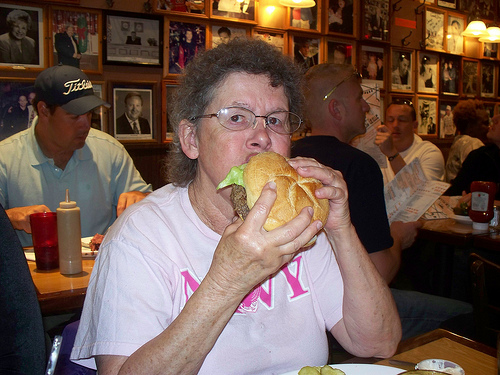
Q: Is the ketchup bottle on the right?
A: Yes, the ketchup bottle is on the right of the image.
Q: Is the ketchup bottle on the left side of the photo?
A: No, the ketchup bottle is on the right of the image.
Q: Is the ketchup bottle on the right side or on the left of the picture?
A: The ketchup bottle is on the right of the image.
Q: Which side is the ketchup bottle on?
A: The ketchup bottle is on the right of the image.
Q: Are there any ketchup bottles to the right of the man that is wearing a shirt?
A: Yes, there is a ketchup bottle to the right of the man.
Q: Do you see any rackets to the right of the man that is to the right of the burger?
A: No, there is a ketchup bottle to the right of the man.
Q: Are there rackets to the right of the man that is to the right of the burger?
A: No, there is a ketchup bottle to the right of the man.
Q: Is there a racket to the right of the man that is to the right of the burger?
A: No, there is a ketchup bottle to the right of the man.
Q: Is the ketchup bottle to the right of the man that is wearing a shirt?
A: Yes, the ketchup bottle is to the right of the man.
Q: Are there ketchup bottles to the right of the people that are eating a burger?
A: Yes, there is a ketchup bottle to the right of the people.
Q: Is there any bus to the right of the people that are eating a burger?
A: No, there is a ketchup bottle to the right of the people.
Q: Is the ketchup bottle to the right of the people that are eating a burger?
A: Yes, the ketchup bottle is to the right of the people.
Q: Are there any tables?
A: Yes, there is a table.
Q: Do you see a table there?
A: Yes, there is a table.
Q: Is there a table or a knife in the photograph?
A: Yes, there is a table.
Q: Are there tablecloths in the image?
A: No, there are no tablecloths.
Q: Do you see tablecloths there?
A: No, there are no tablecloths.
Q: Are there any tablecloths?
A: No, there are no tablecloths.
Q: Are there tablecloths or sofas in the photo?
A: No, there are no tablecloths or sofas.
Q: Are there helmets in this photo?
A: No, there are no helmets.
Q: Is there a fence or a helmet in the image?
A: No, there are no helmets or fences.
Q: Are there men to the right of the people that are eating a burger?
A: Yes, there is a man to the right of the people.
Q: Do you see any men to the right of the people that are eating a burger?
A: Yes, there is a man to the right of the people.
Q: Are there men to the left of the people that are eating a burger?
A: No, the man is to the right of the people.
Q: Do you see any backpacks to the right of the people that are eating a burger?
A: No, there is a man to the right of the people.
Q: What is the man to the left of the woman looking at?
A: The man is looking at the menu.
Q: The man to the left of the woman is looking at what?
A: The man is looking at the menu.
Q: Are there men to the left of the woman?
A: Yes, there is a man to the left of the woman.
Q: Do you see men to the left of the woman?
A: Yes, there is a man to the left of the woman.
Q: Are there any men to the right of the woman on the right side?
A: No, the man is to the left of the woman.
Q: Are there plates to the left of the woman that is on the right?
A: No, there is a man to the left of the woman.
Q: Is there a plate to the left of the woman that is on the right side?
A: No, there is a man to the left of the woman.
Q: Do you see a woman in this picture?
A: Yes, there is a woman.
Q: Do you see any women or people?
A: Yes, there is a woman.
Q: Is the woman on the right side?
A: Yes, the woman is on the right of the image.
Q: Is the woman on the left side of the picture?
A: No, the woman is on the right of the image.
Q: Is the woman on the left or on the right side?
A: The woman is on the right of the image.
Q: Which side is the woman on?
A: The woman is on the right of the image.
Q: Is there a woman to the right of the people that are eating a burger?
A: Yes, there is a woman to the right of the people.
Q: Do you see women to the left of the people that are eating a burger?
A: No, the woman is to the right of the people.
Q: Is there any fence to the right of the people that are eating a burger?
A: No, there is a woman to the right of the people.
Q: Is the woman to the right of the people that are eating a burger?
A: Yes, the woman is to the right of the people.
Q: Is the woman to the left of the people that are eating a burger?
A: No, the woman is to the right of the people.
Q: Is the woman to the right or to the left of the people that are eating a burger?
A: The woman is to the right of the people.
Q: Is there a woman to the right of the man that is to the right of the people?
A: Yes, there is a woman to the right of the man.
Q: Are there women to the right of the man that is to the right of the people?
A: Yes, there is a woman to the right of the man.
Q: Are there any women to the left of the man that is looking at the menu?
A: No, the woman is to the right of the man.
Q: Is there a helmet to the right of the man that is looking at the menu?
A: No, there is a woman to the right of the man.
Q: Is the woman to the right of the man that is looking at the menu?
A: Yes, the woman is to the right of the man.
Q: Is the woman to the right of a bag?
A: No, the woman is to the right of the man.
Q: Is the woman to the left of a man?
A: No, the woman is to the right of a man.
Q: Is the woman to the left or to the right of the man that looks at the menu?
A: The woman is to the right of the man.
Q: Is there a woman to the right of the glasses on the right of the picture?
A: Yes, there is a woman to the right of the glasses.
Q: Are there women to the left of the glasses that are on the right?
A: No, the woman is to the right of the glasses.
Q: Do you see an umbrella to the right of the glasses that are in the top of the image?
A: No, there is a woman to the right of the glasses.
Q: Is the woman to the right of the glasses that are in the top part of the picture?
A: Yes, the woman is to the right of the glasses.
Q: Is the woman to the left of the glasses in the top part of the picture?
A: No, the woman is to the right of the glasses.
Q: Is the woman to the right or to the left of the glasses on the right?
A: The woman is to the right of the glasses.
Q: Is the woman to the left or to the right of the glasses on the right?
A: The woman is to the right of the glasses.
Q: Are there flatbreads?
A: No, there are no flatbreads.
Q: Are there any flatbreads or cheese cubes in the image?
A: No, there are no flatbreads or cheese cubes.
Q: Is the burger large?
A: Yes, the burger is large.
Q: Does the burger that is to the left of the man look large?
A: Yes, the burger is large.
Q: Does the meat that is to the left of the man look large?
A: Yes, the burger is large.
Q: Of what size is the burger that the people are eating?
A: The burger is large.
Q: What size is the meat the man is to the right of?
A: The burger is large.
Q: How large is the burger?
A: The burger is large.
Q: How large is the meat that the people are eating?
A: The burger is large.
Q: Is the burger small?
A: No, the burger is large.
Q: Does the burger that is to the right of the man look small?
A: No, the burger is large.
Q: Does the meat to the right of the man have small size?
A: No, the burger is large.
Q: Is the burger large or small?
A: The burger is large.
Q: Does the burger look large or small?
A: The burger is large.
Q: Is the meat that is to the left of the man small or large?
A: The burger is large.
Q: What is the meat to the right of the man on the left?
A: The meat is a burger.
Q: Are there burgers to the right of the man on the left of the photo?
A: Yes, there is a burger to the right of the man.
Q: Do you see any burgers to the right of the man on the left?
A: Yes, there is a burger to the right of the man.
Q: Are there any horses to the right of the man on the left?
A: No, there is a burger to the right of the man.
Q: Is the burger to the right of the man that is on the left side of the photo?
A: Yes, the burger is to the right of the man.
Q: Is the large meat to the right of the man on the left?
A: Yes, the burger is to the right of the man.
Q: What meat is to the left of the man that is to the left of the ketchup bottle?
A: The meat is a burger.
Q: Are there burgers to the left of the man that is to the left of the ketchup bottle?
A: Yes, there is a burger to the left of the man.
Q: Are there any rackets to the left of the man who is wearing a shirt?
A: No, there is a burger to the left of the man.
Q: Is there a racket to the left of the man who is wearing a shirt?
A: No, there is a burger to the left of the man.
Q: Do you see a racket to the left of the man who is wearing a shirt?
A: No, there is a burger to the left of the man.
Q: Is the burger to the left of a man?
A: Yes, the burger is to the left of a man.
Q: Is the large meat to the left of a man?
A: Yes, the burger is to the left of a man.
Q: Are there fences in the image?
A: No, there are no fences.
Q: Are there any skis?
A: No, there are no skis.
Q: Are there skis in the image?
A: No, there are no skis.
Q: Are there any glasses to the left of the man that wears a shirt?
A: Yes, there are glasses to the left of the man.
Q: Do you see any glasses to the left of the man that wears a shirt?
A: Yes, there are glasses to the left of the man.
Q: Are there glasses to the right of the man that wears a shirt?
A: No, the glasses are to the left of the man.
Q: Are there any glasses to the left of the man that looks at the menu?
A: Yes, there are glasses to the left of the man.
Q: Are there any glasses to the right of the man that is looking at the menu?
A: No, the glasses are to the left of the man.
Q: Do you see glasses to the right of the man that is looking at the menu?
A: No, the glasses are to the left of the man.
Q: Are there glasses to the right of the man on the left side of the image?
A: Yes, there are glasses to the right of the man.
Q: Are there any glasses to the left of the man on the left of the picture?
A: No, the glasses are to the right of the man.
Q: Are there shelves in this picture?
A: No, there are no shelves.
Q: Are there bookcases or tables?
A: Yes, there is a table.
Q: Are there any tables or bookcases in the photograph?
A: Yes, there is a table.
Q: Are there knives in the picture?
A: No, there are no knives.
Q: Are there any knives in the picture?
A: No, there are no knives.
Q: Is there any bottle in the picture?
A: Yes, there is a bottle.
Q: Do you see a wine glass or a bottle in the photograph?
A: Yes, there is a bottle.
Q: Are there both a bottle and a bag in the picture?
A: No, there is a bottle but no bags.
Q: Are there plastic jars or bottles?
A: Yes, there is a plastic bottle.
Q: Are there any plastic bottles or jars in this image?
A: Yes, there is a plastic bottle.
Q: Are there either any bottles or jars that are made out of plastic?
A: Yes, the bottle is made of plastic.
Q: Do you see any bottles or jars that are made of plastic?
A: Yes, the bottle is made of plastic.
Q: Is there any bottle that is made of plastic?
A: Yes, there is a bottle that is made of plastic.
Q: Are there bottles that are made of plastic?
A: Yes, there is a bottle that is made of plastic.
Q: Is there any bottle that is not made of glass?
A: Yes, there is a bottle that is made of plastic.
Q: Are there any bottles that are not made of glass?
A: Yes, there is a bottle that is made of plastic.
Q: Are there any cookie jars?
A: No, there are no cookie jars.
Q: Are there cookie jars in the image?
A: No, there are no cookie jars.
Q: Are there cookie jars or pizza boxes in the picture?
A: No, there are no cookie jars or pizza boxes.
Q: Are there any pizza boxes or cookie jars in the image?
A: No, there are no cookie jars or pizza boxes.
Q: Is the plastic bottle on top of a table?
A: Yes, the bottle is on top of a table.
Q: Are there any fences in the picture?
A: No, there are no fences.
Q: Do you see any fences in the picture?
A: No, there are no fences.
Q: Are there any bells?
A: No, there are no bells.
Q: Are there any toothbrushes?
A: No, there are no toothbrushes.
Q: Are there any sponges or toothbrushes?
A: No, there are no toothbrushes or sponges.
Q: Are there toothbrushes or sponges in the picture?
A: No, there are no toothbrushes or sponges.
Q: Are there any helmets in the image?
A: No, there are no helmets.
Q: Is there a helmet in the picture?
A: No, there are no helmets.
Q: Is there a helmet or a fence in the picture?
A: No, there are no helmets or fences.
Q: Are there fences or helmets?
A: No, there are no helmets or fences.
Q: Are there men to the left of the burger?
A: Yes, there is a man to the left of the burger.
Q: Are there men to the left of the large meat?
A: Yes, there is a man to the left of the burger.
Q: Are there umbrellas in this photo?
A: No, there are no umbrellas.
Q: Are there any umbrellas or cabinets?
A: No, there are no umbrellas or cabinets.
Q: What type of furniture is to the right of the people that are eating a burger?
A: The pieces of furniture are tables.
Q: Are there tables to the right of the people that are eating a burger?
A: Yes, there are tables to the right of the people.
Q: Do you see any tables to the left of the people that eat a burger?
A: No, the tables are to the right of the people.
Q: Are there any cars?
A: No, there are no cars.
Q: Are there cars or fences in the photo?
A: No, there are no cars or fences.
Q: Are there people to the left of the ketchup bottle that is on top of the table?
A: Yes, there are people to the left of the ketchup bottle.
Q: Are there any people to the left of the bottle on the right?
A: Yes, there are people to the left of the ketchup bottle.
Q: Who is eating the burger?
A: The people are eating the burger.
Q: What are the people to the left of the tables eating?
A: The people are eating a burger.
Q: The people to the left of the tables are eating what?
A: The people are eating a burger.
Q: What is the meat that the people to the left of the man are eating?
A: The meat is a burger.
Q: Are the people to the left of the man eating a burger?
A: Yes, the people are eating a burger.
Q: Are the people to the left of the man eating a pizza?
A: No, the people are eating a burger.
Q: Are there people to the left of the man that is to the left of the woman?
A: Yes, there are people to the left of the man.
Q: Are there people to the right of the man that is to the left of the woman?
A: No, the people are to the left of the man.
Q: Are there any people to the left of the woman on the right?
A: Yes, there are people to the left of the woman.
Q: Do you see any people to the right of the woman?
A: No, the people are to the left of the woman.